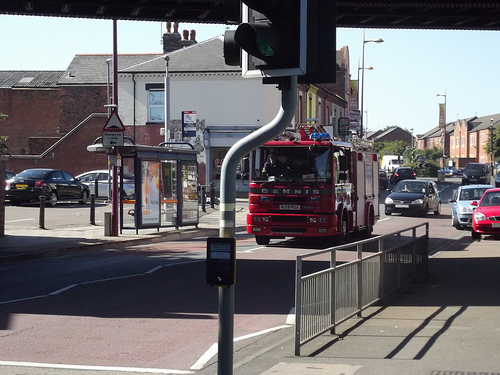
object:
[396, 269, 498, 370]
street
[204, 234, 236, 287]
box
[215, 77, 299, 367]
pole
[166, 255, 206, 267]
line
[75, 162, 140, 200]
car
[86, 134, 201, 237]
bus stop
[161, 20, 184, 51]
chimneys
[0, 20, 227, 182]
building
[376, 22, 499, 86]
sky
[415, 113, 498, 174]
houses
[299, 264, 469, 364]
reflection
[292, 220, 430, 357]
fence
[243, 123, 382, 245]
bus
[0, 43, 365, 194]
assorted buildings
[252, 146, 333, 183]
windshield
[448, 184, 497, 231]
car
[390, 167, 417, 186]
car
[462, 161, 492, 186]
car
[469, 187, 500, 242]
car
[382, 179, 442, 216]
car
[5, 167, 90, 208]
car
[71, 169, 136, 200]
car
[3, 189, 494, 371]
road